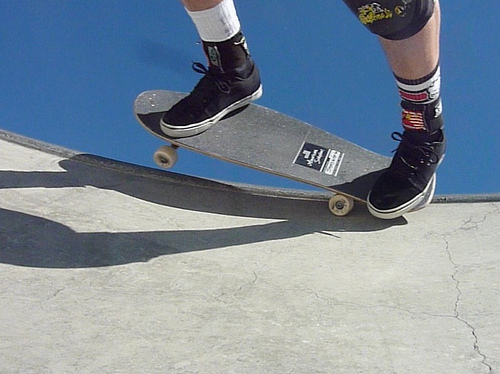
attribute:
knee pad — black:
[342, 1, 439, 40]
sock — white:
[185, 0, 241, 45]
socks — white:
[391, 72, 441, 106]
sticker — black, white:
[287, 130, 359, 180]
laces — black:
[382, 131, 437, 169]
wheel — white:
[317, 192, 357, 218]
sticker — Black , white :
[292, 138, 354, 183]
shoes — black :
[155, 64, 452, 224]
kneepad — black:
[342, 0, 434, 40]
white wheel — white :
[322, 192, 358, 219]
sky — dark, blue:
[51, 16, 478, 188]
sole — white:
[159, 82, 268, 137]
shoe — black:
[153, 43, 441, 235]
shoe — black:
[138, 42, 305, 149]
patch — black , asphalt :
[359, 263, 369, 275]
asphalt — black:
[360, 261, 369, 273]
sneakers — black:
[164, 45, 460, 200]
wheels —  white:
[150, 149, 354, 219]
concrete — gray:
[0, 127, 496, 372]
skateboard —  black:
[134, 86, 436, 215]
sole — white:
[359, 169, 438, 220]